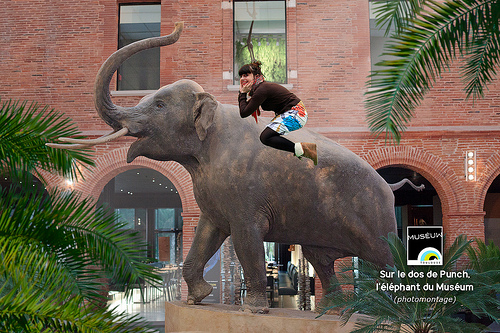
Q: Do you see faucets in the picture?
A: No, there are no faucets.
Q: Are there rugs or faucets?
A: No, there are no faucets or rugs.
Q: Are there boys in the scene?
A: No, there are no boys.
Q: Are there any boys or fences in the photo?
A: No, there are no boys or fences.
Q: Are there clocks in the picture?
A: No, there are no clocks.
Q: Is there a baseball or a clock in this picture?
A: No, there are no clocks or baseballs.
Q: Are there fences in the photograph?
A: No, there are no fences.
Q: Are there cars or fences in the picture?
A: No, there are no fences or cars.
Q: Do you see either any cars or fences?
A: No, there are no fences or cars.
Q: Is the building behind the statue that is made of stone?
A: Yes, the building is behind the statue.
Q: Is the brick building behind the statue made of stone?
A: Yes, the building is behind the statue.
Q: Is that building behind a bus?
A: No, the building is behind the statue.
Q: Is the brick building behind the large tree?
A: Yes, the building is behind the tree.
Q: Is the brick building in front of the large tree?
A: No, the building is behind the tree.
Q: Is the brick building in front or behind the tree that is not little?
A: The building is behind the tree.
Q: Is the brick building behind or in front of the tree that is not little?
A: The building is behind the tree.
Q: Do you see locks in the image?
A: No, there are no locks.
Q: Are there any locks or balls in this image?
A: No, there are no locks or balls.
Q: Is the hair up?
A: Yes, the hair is up.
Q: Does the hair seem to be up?
A: Yes, the hair is up.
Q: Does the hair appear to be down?
A: No, the hair is up.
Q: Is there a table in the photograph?
A: Yes, there is a table.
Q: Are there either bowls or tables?
A: Yes, there is a table.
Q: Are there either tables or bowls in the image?
A: Yes, there is a table.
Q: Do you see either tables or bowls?
A: Yes, there is a table.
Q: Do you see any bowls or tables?
A: Yes, there is a table.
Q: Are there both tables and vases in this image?
A: No, there is a table but no vases.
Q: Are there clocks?
A: No, there are no clocks.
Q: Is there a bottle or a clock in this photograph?
A: No, there are no clocks or bottles.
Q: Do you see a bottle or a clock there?
A: No, there are no clocks or bottles.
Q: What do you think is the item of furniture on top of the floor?
A: The piece of furniture is a table.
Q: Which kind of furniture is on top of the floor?
A: The piece of furniture is a table.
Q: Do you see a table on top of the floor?
A: Yes, there is a table on top of the floor.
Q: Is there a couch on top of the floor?
A: No, there is a table on top of the floor.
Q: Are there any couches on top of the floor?
A: No, there is a table on top of the floor.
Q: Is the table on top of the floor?
A: Yes, the table is on top of the floor.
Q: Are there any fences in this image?
A: No, there are no fences.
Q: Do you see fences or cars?
A: No, there are no fences or cars.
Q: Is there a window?
A: Yes, there is a window.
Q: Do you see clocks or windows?
A: Yes, there is a window.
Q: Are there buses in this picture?
A: No, there are no buses.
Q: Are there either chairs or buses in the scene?
A: No, there are no buses or chairs.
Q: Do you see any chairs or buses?
A: No, there are no buses or chairs.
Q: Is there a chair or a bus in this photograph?
A: No, there are no buses or chairs.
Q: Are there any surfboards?
A: No, there are no surfboards.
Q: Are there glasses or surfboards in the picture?
A: No, there are no surfboards or glasses.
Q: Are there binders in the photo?
A: No, there are no binders.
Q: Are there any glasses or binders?
A: No, there are no binders or glasses.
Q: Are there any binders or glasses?
A: No, there are no binders or glasses.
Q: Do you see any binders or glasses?
A: No, there are no binders or glasses.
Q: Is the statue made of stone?
A: Yes, the statue is made of stone.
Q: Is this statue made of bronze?
A: No, the statue is made of stone.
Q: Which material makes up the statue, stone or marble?
A: The statue is made of stone.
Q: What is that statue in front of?
A: The statue is in front of the building.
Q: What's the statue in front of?
A: The statue is in front of the building.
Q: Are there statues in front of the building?
A: Yes, there is a statue in front of the building.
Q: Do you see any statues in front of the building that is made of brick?
A: Yes, there is a statue in front of the building.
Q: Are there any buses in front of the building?
A: No, there is a statue in front of the building.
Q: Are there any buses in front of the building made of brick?
A: No, there is a statue in front of the building.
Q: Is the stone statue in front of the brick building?
A: Yes, the statue is in front of the building.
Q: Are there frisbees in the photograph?
A: No, there are no frisbees.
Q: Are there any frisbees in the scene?
A: No, there are no frisbees.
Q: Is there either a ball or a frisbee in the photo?
A: No, there are no frisbees or balls.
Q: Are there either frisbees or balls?
A: No, there are no frisbees or balls.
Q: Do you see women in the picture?
A: Yes, there is a woman.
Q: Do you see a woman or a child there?
A: Yes, there is a woman.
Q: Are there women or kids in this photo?
A: Yes, there is a woman.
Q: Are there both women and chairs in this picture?
A: No, there is a woman but no chairs.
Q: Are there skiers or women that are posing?
A: Yes, the woman is posing.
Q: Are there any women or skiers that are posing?
A: Yes, the woman is posing.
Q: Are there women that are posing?
A: Yes, there is a woman that is posing.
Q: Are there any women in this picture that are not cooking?
A: Yes, there is a woman that is posing.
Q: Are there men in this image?
A: No, there are no men.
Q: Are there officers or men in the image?
A: No, there are no men or officers.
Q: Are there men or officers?
A: No, there are no men or officers.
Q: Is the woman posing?
A: Yes, the woman is posing.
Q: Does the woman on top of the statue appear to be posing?
A: Yes, the woman is posing.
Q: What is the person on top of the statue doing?
A: The woman is posing.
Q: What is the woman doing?
A: The woman is posing.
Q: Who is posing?
A: The woman is posing.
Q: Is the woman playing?
A: No, the woman is posing.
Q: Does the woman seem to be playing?
A: No, the woman is posing.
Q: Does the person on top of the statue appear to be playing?
A: No, the woman is posing.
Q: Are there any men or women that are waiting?
A: No, there is a woman but she is posing.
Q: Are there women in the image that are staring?
A: No, there is a woman but she is posing.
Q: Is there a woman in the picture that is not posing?
A: No, there is a woman but she is posing.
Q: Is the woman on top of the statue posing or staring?
A: The woman is posing.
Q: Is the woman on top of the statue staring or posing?
A: The woman is posing.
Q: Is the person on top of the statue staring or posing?
A: The woman is posing.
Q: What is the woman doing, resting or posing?
A: The woman is posing.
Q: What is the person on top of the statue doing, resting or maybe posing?
A: The woman is posing.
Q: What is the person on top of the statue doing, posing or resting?
A: The woman is posing.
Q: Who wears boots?
A: The woman wears boots.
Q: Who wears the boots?
A: The woman wears boots.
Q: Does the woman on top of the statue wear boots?
A: Yes, the woman wears boots.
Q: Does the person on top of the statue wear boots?
A: Yes, the woman wears boots.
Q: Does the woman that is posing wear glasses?
A: No, the woman wears boots.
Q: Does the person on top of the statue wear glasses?
A: No, the woman wears boots.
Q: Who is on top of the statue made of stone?
A: The woman is on top of the statue.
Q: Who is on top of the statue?
A: The woman is on top of the statue.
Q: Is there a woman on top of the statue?
A: Yes, there is a woman on top of the statue.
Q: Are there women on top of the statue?
A: Yes, there is a woman on top of the statue.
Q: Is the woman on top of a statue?
A: Yes, the woman is on top of a statue.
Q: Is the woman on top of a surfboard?
A: No, the woman is on top of a statue.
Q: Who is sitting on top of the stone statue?
A: The woman is sitting on top of the statue.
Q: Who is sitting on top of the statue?
A: The woman is sitting on top of the statue.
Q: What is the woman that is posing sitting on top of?
A: The woman is sitting on top of the statue.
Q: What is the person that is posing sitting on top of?
A: The woman is sitting on top of the statue.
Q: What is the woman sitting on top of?
A: The woman is sitting on top of the statue.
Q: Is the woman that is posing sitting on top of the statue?
A: Yes, the woman is sitting on top of the statue.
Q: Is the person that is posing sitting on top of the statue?
A: Yes, the woman is sitting on top of the statue.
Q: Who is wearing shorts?
A: The woman is wearing shorts.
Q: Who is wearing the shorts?
A: The woman is wearing shorts.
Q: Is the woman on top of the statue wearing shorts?
A: Yes, the woman is wearing shorts.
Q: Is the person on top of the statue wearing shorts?
A: Yes, the woman is wearing shorts.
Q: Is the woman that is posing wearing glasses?
A: No, the woman is wearing shorts.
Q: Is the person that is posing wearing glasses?
A: No, the woman is wearing shorts.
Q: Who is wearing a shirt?
A: The woman is wearing a shirt.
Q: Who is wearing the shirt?
A: The woman is wearing a shirt.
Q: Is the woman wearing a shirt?
A: Yes, the woman is wearing a shirt.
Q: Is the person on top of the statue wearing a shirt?
A: Yes, the woman is wearing a shirt.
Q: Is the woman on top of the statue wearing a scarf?
A: No, the woman is wearing a shirt.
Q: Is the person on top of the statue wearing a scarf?
A: No, the woman is wearing a shirt.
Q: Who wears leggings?
A: The woman wears leggings.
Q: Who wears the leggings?
A: The woman wears leggings.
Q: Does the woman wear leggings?
A: Yes, the woman wears leggings.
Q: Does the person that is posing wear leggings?
A: Yes, the woman wears leggings.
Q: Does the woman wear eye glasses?
A: No, the woman wears leggings.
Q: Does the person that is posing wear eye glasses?
A: No, the woman wears leggings.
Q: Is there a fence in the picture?
A: No, there are no fences.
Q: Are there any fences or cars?
A: No, there are no fences or cars.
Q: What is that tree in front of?
A: The tree is in front of the building.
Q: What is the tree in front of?
A: The tree is in front of the building.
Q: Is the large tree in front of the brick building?
A: Yes, the tree is in front of the building.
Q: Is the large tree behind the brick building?
A: No, the tree is in front of the building.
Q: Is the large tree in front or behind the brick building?
A: The tree is in front of the building.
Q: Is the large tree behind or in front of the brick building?
A: The tree is in front of the building.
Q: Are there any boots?
A: Yes, there are boots.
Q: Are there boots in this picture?
A: Yes, there are boots.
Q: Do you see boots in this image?
A: Yes, there are boots.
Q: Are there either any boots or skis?
A: Yes, there are boots.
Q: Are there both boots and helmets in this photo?
A: No, there are boots but no helmets.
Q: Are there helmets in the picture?
A: No, there are no helmets.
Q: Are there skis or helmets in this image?
A: No, there are no helmets or skis.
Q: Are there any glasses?
A: No, there are no glasses.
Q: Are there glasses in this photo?
A: No, there are no glasses.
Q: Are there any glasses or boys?
A: No, there are no glasses or boys.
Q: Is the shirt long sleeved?
A: Yes, the shirt is long sleeved.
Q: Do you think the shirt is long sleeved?
A: Yes, the shirt is long sleeved.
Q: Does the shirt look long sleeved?
A: Yes, the shirt is long sleeved.